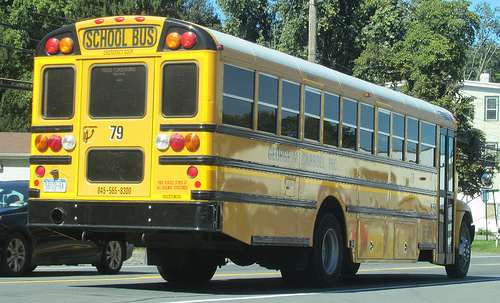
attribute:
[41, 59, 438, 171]
windows — black, tinted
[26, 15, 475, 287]
bus — yellow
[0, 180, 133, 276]
car — black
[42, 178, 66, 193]
plate — colored